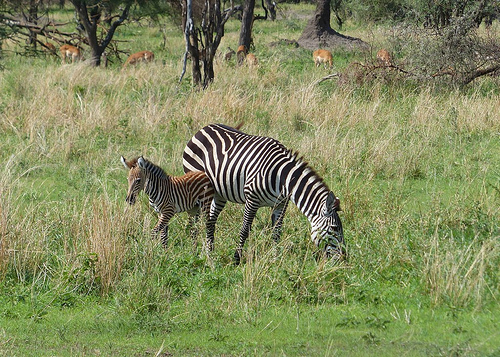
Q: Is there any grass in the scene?
A: Yes, there is grass.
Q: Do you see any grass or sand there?
A: Yes, there is grass.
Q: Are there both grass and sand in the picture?
A: No, there is grass but no sand.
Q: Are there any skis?
A: No, there are no skis.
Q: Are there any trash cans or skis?
A: No, there are no skis or trash cans.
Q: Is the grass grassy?
A: Yes, the grass is grassy.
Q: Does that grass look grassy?
A: Yes, the grass is grassy.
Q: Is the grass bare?
A: No, the grass is grassy.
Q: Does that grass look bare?
A: No, the grass is grassy.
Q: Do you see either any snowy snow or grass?
A: No, there is grass but it is grassy.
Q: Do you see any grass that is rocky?
A: No, there is grass but it is grassy.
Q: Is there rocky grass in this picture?
A: No, there is grass but it is grassy.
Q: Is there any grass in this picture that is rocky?
A: No, there is grass but it is grassy.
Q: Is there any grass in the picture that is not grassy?
A: No, there is grass but it is grassy.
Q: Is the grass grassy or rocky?
A: The grass is grassy.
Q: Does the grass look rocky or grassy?
A: The grass is grassy.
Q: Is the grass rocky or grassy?
A: The grass is grassy.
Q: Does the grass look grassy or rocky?
A: The grass is grassy.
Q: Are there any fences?
A: No, there are no fences.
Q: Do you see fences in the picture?
A: No, there are no fences.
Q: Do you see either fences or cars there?
A: No, there are no fences or cars.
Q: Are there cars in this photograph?
A: No, there are no cars.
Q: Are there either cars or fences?
A: No, there are no cars or fences.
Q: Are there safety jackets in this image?
A: No, there are no safety jackets.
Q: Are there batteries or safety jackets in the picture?
A: No, there are no safety jackets or batteries.